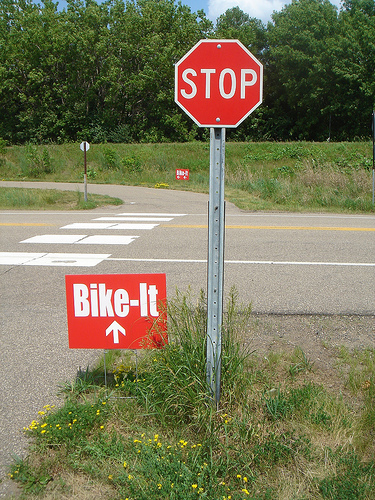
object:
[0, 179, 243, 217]
bike trail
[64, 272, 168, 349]
red sign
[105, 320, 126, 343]
white arrow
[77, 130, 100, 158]
sign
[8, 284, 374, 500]
grass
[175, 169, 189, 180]
sign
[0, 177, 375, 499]
road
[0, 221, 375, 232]
line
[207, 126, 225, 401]
pole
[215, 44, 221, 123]
bolts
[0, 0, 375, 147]
trees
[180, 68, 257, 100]
lettering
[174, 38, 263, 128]
sign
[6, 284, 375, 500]
trees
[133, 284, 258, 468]
bush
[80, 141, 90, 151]
sign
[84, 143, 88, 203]
pole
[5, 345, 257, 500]
dandelion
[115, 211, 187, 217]
line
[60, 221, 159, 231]
line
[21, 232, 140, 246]
line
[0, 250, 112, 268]
line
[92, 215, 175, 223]
line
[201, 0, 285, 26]
clouds